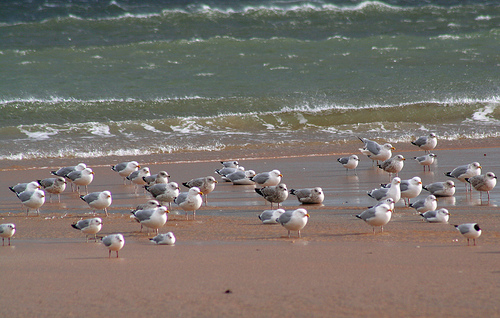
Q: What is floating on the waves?
A: Sea foam.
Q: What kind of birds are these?
A: Seagulls.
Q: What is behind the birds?
A: The ocean.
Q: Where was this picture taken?
A: A beach.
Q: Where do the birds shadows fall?
A: To the left.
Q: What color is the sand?
A: Dark Pink.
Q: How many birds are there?
A: Forty.